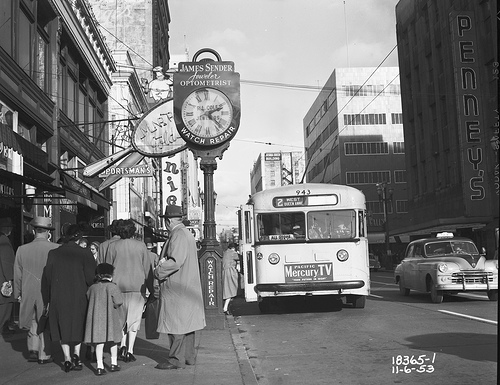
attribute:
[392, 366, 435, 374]
photo date — 11/6/1953, 1953, 1950s, 11-6-53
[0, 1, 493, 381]
photo — black, white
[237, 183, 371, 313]
bus — parked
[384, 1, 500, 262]
building — multistoried, tall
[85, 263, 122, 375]
child — standing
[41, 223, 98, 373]
woman — walking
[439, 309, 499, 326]
street line — white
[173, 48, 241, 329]
clock — black, white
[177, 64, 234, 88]
ad — for optomitrist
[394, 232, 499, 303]
taxi cab — driving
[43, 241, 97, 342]
coat — long